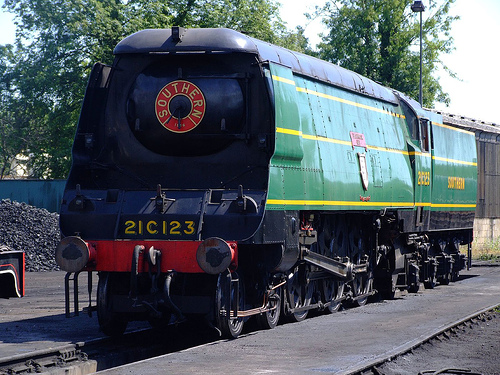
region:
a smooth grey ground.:
[321, 301, 381, 366]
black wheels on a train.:
[212, 245, 375, 336]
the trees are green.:
[5, 0, 75, 123]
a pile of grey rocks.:
[9, 202, 54, 248]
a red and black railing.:
[0, 244, 42, 300]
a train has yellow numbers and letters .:
[413, 165, 476, 196]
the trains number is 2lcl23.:
[118, 216, 198, 246]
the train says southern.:
[142, 70, 221, 154]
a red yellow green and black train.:
[51, 1, 487, 356]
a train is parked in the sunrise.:
[26, 4, 483, 374]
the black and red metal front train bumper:
[54, 236, 93, 268]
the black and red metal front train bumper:
[192, 233, 229, 267]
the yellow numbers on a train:
[123, 218, 193, 240]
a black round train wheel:
[220, 264, 249, 334]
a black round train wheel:
[262, 273, 282, 324]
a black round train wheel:
[287, 268, 318, 318]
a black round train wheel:
[318, 256, 348, 310]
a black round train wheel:
[348, 253, 376, 305]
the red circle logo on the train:
[155, 79, 204, 131]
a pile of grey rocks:
[1, 199, 65, 269]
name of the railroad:
[154, 78, 216, 135]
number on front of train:
[121, 215, 210, 240]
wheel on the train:
[225, 277, 255, 337]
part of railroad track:
[52, 341, 140, 361]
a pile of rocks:
[4, 213, 45, 235]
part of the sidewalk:
[297, 309, 392, 354]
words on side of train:
[437, 167, 482, 197]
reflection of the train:
[12, 310, 72, 340]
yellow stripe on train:
[287, 114, 332, 146]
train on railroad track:
[50, 30, 487, 310]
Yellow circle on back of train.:
[142, 75, 230, 162]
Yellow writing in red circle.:
[158, 83, 203, 136]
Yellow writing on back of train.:
[122, 213, 227, 253]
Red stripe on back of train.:
[68, 210, 232, 278]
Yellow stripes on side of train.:
[290, 111, 400, 160]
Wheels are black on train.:
[261, 231, 451, 262]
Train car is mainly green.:
[306, 98, 428, 213]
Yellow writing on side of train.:
[441, 164, 468, 212]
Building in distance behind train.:
[468, 109, 489, 237]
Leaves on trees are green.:
[24, 77, 72, 145]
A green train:
[53, 23, 466, 338]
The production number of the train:
[115, 212, 195, 237]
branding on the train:
[150, 65, 210, 131]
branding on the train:
[445, 170, 475, 192]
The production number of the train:
[418, 169, 433, 187]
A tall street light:
[401, 0, 433, 100]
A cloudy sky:
[0, 0, 492, 118]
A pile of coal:
[2, 201, 71, 266]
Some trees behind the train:
[5, 0, 460, 175]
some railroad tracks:
[1, 255, 497, 373]